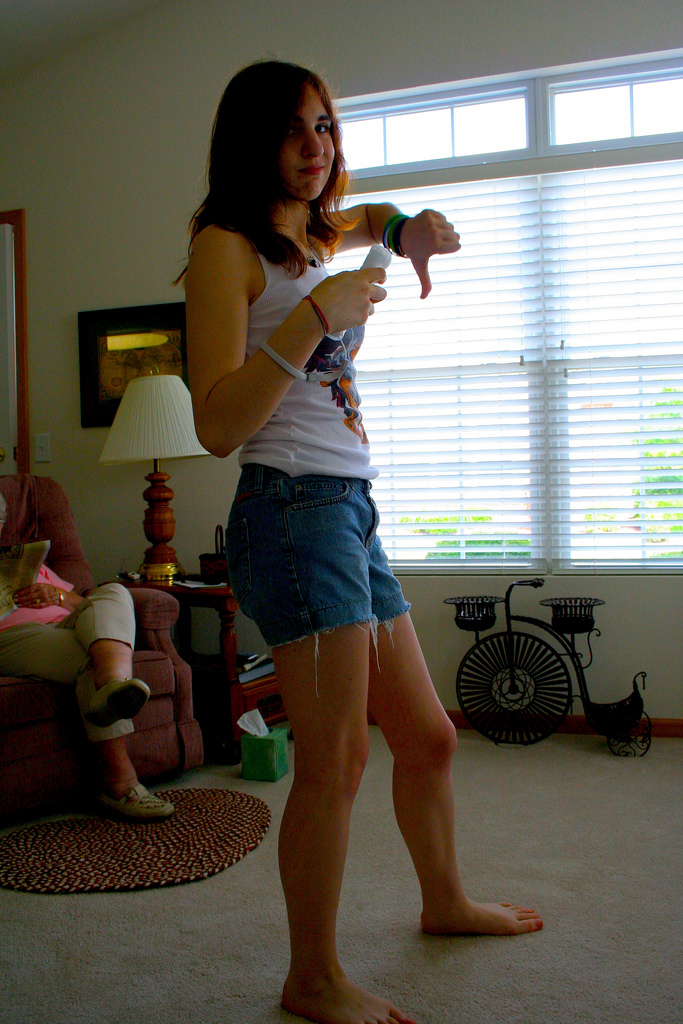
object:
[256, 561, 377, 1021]
leg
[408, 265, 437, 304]
thumb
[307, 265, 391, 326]
hand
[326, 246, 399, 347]
wii remote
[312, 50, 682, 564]
window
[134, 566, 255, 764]
table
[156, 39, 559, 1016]
woman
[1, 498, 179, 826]
woman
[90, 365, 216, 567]
lamp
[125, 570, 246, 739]
table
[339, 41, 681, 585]
blinds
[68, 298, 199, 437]
artwork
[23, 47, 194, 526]
wall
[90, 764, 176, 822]
foot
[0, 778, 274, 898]
rug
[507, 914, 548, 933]
toes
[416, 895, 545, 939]
foot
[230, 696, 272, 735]
tissue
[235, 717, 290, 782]
box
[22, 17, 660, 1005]
living room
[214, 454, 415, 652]
shorts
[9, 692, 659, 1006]
carpet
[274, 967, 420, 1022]
foot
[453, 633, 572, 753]
wheel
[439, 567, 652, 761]
cart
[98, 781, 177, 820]
shoe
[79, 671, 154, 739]
foot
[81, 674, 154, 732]
shoe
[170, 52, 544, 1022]
human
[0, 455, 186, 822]
human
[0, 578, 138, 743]
pants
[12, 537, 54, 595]
newspaper